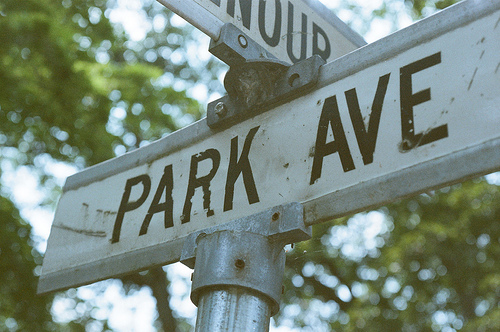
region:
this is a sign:
[46, 0, 497, 299]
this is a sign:
[180, 0, 370, 67]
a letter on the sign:
[89, 174, 151, 250]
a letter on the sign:
[138, 153, 191, 248]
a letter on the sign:
[183, 148, 230, 230]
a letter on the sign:
[214, 116, 269, 211]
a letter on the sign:
[288, 88, 363, 188]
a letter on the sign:
[344, 67, 393, 162]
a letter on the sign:
[379, 38, 465, 166]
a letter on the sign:
[285, 2, 319, 71]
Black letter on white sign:
[95, 175, 145, 267]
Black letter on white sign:
[395, 54, 471, 157]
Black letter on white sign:
[337, 73, 400, 153]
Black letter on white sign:
[296, 87, 364, 192]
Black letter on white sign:
[215, 130, 282, 206]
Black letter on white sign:
[173, 145, 228, 225]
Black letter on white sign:
[140, 168, 186, 243]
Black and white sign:
[32, 158, 400, 228]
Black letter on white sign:
[312, 10, 338, 70]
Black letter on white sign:
[285, 0, 310, 72]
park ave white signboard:
[37, 5, 498, 280]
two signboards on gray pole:
[45, 6, 496, 293]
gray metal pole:
[198, 59, 300, 330]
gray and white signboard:
[44, 0, 496, 301]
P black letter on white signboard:
[104, 175, 146, 242]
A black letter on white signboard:
[141, 159, 182, 233]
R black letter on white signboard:
[180, 146, 224, 220]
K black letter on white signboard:
[222, 121, 262, 215]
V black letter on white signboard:
[340, 71, 392, 165]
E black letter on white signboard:
[400, 53, 454, 150]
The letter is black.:
[92, 166, 154, 246]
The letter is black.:
[138, 158, 179, 238]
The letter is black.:
[180, 144, 218, 224]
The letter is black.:
[218, 120, 270, 215]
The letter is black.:
[299, 84, 357, 187]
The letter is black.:
[338, 65, 398, 169]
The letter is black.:
[390, 43, 456, 148]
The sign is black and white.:
[20, 5, 495, 326]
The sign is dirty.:
[3, 0, 498, 298]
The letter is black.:
[283, 1, 314, 68]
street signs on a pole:
[87, 69, 493, 271]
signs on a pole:
[109, 34, 403, 319]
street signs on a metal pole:
[79, 47, 385, 327]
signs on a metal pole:
[94, 52, 400, 329]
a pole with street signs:
[121, 51, 368, 323]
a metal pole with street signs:
[114, 51, 457, 315]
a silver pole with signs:
[89, 43, 354, 325]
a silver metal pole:
[54, 4, 464, 326]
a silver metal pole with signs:
[112, 36, 440, 325]